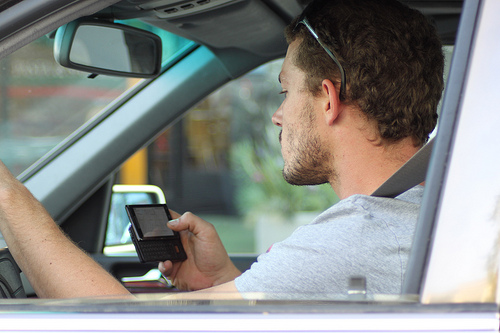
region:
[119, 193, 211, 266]
hand holding a cell phone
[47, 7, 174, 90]
a car's rear view mirror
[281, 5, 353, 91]
sun glasses on top of a head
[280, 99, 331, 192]
a beard on a man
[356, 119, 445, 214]
seat belt in a car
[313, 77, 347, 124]
ear on a head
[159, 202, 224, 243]
thumb on a hand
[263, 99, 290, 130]
a nose on a person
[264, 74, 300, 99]
eye of a person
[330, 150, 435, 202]
neck of a person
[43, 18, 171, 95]
A rear view mirror in the car.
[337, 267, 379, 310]
A lock for the driver's side door.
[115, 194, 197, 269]
A black smart phone held by the man.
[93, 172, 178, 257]
The passenger side mirror on the car.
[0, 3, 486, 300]
The driver's side window that is down.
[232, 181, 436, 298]
A grey shirt on the man.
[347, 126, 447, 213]
A grey seat belt on the man.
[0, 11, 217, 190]
Front windshield on the car.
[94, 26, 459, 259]
The passenger side window is currently open.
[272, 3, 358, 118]
Black sun glasses on the man's head.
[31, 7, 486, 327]
a man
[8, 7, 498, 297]
a man in a car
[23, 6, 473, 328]
a man looking at a cellphone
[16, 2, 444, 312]
a man looks at a cellphone in a car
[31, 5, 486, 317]
a man uses a cellphone while driving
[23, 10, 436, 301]
a man looks at a cellphone while driving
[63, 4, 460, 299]
the man has glasses on his head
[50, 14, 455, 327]
the man is wearing a grey shirt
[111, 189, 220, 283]
the cellphone has a touch screen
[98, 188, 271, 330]
the cellphone has a slide out keyboard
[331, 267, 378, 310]
window lock at side of car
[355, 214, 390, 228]
small round spot on gray shirt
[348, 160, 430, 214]
gray sleep belt around man's neck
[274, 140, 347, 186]
fuzzy beard on man's face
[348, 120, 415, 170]
edge of man's haircut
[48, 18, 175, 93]
front mirror in car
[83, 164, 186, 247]
white edge of passenger mirror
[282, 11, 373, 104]
edge of glasses on man's head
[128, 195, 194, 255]
black smart phone in man's hand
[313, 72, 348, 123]
large white ears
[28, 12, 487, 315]
a man driving a car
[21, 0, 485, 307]
a man in drivers seat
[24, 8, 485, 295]
man wearing a seatbelt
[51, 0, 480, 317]
a man on his phone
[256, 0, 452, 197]
man with sunglasses on his head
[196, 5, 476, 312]
man in a grey shirt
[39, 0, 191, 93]
a rear view mirror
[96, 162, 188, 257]
a car side mirror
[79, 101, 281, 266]
a blurry background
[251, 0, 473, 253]
a brown haired man